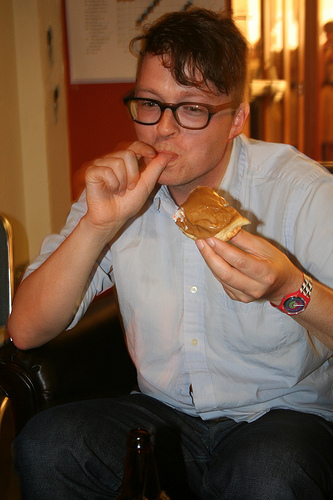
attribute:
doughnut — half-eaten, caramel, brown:
[163, 184, 252, 251]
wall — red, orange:
[60, 1, 234, 201]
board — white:
[61, 0, 232, 94]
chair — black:
[0, 264, 137, 443]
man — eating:
[18, 10, 322, 500]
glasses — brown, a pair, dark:
[121, 88, 235, 132]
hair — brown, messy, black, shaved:
[159, 10, 249, 91]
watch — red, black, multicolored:
[274, 269, 322, 319]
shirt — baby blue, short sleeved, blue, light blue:
[96, 172, 322, 420]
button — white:
[182, 281, 207, 297]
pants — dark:
[36, 391, 327, 496]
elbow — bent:
[4, 313, 54, 357]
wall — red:
[79, 96, 116, 139]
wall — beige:
[10, 51, 48, 209]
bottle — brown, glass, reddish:
[118, 416, 171, 497]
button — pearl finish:
[183, 336, 206, 349]